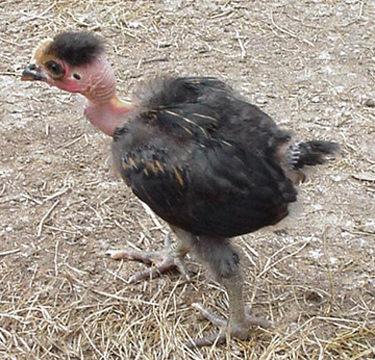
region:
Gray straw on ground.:
[28, 315, 137, 356]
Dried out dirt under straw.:
[21, 148, 88, 225]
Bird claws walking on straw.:
[107, 250, 193, 282]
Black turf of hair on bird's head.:
[48, 33, 110, 63]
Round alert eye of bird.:
[42, 62, 62, 78]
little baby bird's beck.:
[19, 61, 47, 82]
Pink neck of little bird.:
[75, 67, 134, 127]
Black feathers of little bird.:
[110, 84, 343, 234]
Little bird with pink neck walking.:
[17, 30, 343, 352]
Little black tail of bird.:
[294, 138, 341, 169]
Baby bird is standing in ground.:
[19, 21, 295, 340]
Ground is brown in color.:
[10, 19, 322, 330]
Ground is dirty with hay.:
[10, 16, 366, 344]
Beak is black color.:
[10, 58, 49, 89]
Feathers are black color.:
[132, 91, 273, 231]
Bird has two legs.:
[102, 222, 285, 348]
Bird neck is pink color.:
[68, 52, 131, 143]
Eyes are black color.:
[44, 58, 63, 77]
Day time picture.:
[12, 14, 357, 348]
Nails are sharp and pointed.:
[95, 243, 205, 295]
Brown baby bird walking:
[20, 26, 310, 353]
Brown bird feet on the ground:
[102, 230, 280, 354]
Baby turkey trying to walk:
[16, 25, 325, 353]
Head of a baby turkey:
[14, 31, 134, 146]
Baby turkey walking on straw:
[15, 28, 328, 345]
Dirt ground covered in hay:
[8, 194, 115, 359]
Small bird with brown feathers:
[17, 38, 333, 246]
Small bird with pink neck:
[9, 32, 164, 140]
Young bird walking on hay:
[13, 20, 371, 338]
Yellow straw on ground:
[22, 321, 102, 359]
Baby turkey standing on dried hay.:
[6, 5, 349, 341]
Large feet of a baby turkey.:
[99, 191, 279, 359]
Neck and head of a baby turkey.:
[5, 26, 139, 151]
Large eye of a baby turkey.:
[32, 48, 73, 90]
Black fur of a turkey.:
[117, 70, 335, 236]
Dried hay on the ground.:
[19, 175, 329, 356]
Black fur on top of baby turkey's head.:
[41, 20, 112, 80]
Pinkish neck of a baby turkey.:
[47, 55, 138, 139]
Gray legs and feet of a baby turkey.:
[81, 192, 294, 350]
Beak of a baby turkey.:
[15, 53, 64, 93]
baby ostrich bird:
[19, 23, 338, 341]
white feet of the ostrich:
[121, 235, 272, 353]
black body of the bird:
[120, 80, 303, 230]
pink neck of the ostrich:
[85, 95, 136, 127]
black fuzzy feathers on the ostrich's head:
[42, 32, 100, 63]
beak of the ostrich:
[18, 65, 44, 86]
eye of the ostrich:
[44, 63, 61, 76]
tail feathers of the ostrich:
[291, 137, 333, 169]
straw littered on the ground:
[3, 5, 374, 356]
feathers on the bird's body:
[107, 74, 289, 229]